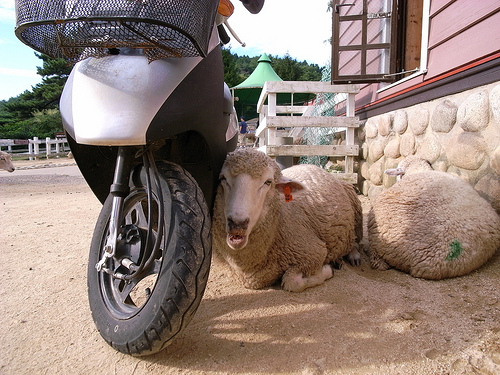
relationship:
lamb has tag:
[222, 141, 356, 286] [268, 192, 307, 207]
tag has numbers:
[268, 192, 307, 207] [282, 185, 287, 202]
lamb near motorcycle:
[222, 141, 356, 286] [16, 6, 288, 364]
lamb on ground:
[222, 141, 356, 286] [218, 299, 470, 357]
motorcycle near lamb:
[16, 6, 288, 364] [222, 141, 356, 286]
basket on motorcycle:
[15, 2, 233, 65] [16, 6, 288, 364]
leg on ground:
[282, 254, 335, 289] [218, 299, 470, 357]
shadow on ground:
[160, 303, 470, 373] [218, 299, 470, 357]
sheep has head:
[1, 146, 26, 180] [0, 151, 15, 173]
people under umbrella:
[236, 113, 263, 148] [211, 40, 288, 100]